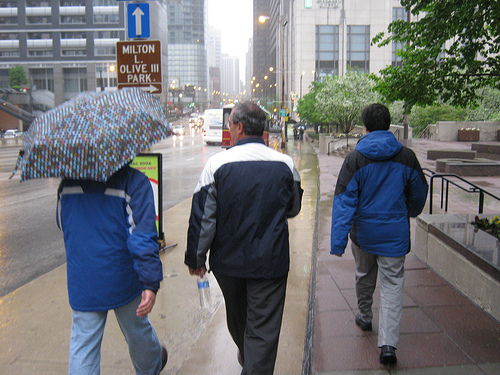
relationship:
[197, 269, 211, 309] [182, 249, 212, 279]
bottle in hand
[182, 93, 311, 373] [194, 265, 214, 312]
man holding bottle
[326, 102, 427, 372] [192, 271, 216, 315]
man holding water bottle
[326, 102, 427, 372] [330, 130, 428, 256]
man wearing coat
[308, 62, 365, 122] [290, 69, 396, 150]
flowers on tree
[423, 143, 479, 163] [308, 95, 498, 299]
bench in park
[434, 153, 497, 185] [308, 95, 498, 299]
bench in park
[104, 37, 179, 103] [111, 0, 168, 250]
sign on pole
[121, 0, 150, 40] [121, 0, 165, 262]
sign on pole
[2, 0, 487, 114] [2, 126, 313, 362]
buildings on street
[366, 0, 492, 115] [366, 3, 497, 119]
leaves on branches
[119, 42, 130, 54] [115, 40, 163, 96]
letter on sign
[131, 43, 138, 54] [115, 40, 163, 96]
letter on sign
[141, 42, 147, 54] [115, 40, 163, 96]
letter on sign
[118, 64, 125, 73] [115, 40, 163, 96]
letter on sign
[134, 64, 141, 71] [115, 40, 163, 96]
letter on sign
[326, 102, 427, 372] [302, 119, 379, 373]
man on sidewalk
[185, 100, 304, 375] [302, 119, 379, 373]
man on sidewalk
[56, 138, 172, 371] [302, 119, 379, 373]
man on sidewalk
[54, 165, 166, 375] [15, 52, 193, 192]
man holding umbrella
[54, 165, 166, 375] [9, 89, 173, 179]
man under umbrella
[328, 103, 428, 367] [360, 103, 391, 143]
man has hair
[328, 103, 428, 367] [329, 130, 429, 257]
man wearing coat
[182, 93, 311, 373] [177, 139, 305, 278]
man wearing jacket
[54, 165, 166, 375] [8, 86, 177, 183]
man walking under an colored umbrella